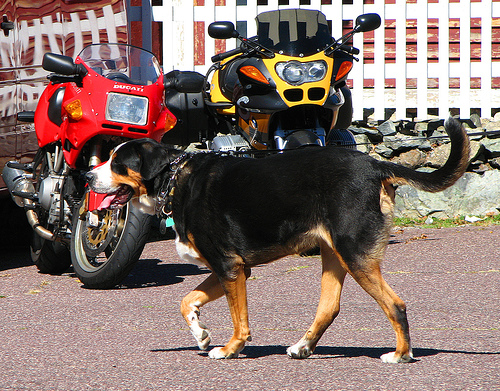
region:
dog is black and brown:
[92, 120, 467, 363]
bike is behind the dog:
[212, 8, 390, 150]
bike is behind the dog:
[27, 45, 202, 288]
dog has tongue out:
[95, 184, 127, 211]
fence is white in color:
[375, 1, 470, 84]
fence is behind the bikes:
[360, 1, 495, 129]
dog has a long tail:
[386, 116, 473, 191]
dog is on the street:
[88, 129, 468, 366]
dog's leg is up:
[174, 294, 224, 358]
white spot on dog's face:
[85, 153, 116, 189]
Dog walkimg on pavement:
[89, 116, 464, 390]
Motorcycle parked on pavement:
[0, 23, 187, 306]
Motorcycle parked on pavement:
[201, 17, 375, 239]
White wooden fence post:
[453, 0, 481, 129]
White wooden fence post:
[436, 1, 454, 124]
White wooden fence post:
[413, 4, 435, 120]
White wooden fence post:
[392, 1, 416, 131]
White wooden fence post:
[372, 2, 386, 138]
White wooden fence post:
[193, 1, 223, 86]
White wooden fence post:
[223, 1, 242, 56]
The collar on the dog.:
[156, 152, 187, 218]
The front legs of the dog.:
[180, 268, 255, 359]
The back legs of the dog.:
[292, 253, 413, 363]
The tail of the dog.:
[390, 117, 468, 194]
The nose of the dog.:
[85, 168, 97, 178]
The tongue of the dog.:
[95, 191, 113, 208]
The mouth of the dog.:
[103, 187, 130, 202]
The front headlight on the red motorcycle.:
[105, 96, 150, 121]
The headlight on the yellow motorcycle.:
[280, 62, 320, 80]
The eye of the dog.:
[112, 155, 124, 167]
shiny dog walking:
[79, 119, 471, 365]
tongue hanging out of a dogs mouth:
[83, 138, 165, 218]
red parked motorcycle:
[3, 40, 180, 290]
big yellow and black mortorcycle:
[161, 7, 385, 267]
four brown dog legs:
[165, 244, 424, 365]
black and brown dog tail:
[368, 116, 472, 196]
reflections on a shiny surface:
[1, 0, 156, 200]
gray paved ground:
[3, 225, 499, 390]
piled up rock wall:
[353, 117, 499, 226]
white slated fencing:
[166, 0, 499, 122]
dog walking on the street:
[55, 103, 483, 382]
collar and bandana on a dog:
[150, 128, 201, 224]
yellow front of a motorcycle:
[250, 45, 342, 117]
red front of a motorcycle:
[57, 61, 172, 138]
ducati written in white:
[104, 75, 152, 97]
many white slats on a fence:
[377, 14, 464, 75]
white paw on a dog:
[280, 328, 318, 366]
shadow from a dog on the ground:
[330, 346, 362, 360]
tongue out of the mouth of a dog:
[87, 189, 133, 214]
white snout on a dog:
[83, 161, 117, 198]